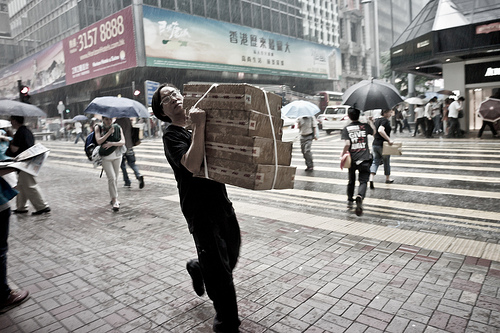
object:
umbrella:
[406, 95, 426, 109]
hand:
[416, 92, 433, 116]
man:
[296, 109, 320, 174]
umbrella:
[278, 97, 322, 117]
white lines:
[399, 135, 499, 229]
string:
[191, 81, 279, 191]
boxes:
[380, 143, 402, 156]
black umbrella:
[339, 77, 404, 110]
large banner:
[61, 12, 128, 79]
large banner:
[3, 55, 67, 84]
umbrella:
[477, 95, 499, 125]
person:
[467, 96, 498, 138]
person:
[5, 111, 59, 216]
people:
[52, 28, 497, 292]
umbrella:
[0, 87, 48, 121]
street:
[2, 94, 497, 331]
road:
[29, 126, 498, 247]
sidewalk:
[69, 226, 158, 323]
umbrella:
[82, 89, 151, 119]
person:
[151, 78, 242, 331]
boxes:
[181, 81, 297, 190]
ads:
[143, 24, 307, 70]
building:
[228, 0, 365, 46]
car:
[321, 105, 350, 131]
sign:
[16, 73, 103, 142]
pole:
[49, 94, 94, 145]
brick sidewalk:
[4, 172, 499, 332]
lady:
[92, 115, 127, 212]